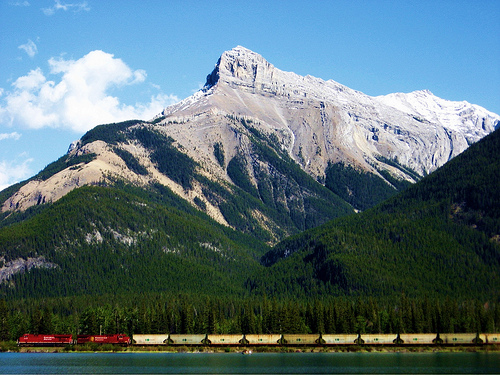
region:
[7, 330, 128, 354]
two red train cars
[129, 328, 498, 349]
train cars are off white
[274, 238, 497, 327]
trees on the mountain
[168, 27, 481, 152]
mountain has no trees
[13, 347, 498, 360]
trees next to the water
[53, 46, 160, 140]
thick puffy white cloud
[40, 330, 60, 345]
white writing on the train car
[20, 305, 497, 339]
trees on other side of train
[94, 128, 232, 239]
trees on parts of the mountain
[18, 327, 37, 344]
window on the train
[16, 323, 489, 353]
the train is long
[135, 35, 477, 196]
a tall gray mountain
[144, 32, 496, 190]
The mountain is grey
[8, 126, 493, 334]
Green trees covering the mountain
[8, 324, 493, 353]
A train by the water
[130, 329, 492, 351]
The train cars are yellow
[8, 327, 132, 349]
The train engines are red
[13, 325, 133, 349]
There are two train engines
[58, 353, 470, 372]
The water is turquoise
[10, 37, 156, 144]
The cloud is white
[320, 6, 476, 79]
A pale blue sky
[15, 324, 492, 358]
The train has many train cars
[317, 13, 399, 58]
this is the sky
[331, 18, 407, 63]
the sky is blue in color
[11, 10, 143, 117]
the sky has clouds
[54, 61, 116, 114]
the clouds are white in color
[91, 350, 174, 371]
this is the water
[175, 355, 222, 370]
the water is blue in color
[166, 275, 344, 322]
this is the grass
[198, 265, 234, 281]
the grass is green in color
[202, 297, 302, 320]
these are some trees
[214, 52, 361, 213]
this is a hill